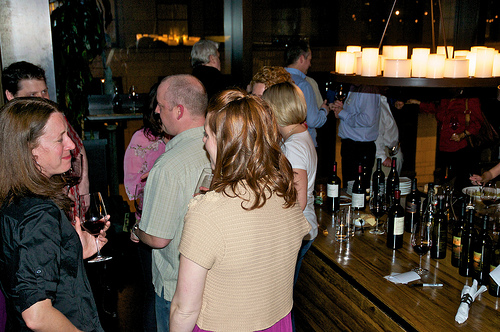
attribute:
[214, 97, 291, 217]
hair — red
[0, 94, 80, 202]
brown hair —  dark brown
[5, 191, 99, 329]
shirt — black , silky 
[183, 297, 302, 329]
dress — purple 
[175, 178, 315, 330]
top — pink , short sleeved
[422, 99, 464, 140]
shirt — red 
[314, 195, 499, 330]
bar top — Wood grain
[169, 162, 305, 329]
sweater — brown 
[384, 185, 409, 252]
wine bottle — red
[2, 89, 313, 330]
women — talking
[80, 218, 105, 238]
red wine — red 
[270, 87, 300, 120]
hair — blonde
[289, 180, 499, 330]
table — brown, wooden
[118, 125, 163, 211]
pink shirt — pink 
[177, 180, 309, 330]
striped shirt — striped 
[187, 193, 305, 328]
shirt — tan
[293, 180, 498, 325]
counter — tan, wooden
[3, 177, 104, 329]
shirt — black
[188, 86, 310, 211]
hair — shiny, brown, curly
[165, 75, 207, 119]
hair — grey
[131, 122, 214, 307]
shirt — mint green